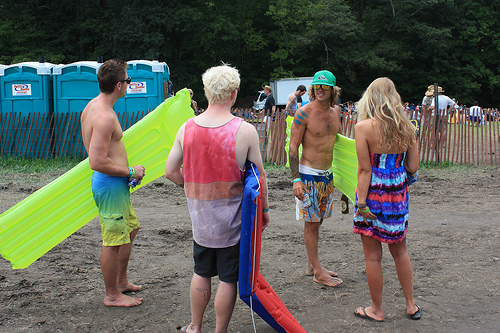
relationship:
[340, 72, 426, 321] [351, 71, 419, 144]
girl has hair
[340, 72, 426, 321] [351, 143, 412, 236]
girl wearing dress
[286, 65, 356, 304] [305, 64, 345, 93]
guy wearing hat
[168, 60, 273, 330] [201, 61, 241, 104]
guy has hair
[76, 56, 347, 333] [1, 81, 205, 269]
guy holding float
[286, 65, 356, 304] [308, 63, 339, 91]
guy wearing hat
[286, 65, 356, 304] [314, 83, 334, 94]
guy wearing goggles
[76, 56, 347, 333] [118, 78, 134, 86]
guy wearing glasses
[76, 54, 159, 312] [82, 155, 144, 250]
man wearing shorts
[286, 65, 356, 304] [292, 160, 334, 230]
guy wearing shorts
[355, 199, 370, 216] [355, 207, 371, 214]
bracelet on bracelet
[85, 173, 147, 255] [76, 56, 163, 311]
shorts worn by guy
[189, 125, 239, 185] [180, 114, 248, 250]
section of tank top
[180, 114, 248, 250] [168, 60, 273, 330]
tank top worn by guy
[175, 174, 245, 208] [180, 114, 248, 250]
section of tank top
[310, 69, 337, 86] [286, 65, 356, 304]
cap worn by guy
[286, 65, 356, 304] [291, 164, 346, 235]
guy in shorts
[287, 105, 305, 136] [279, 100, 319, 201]
stripes on arm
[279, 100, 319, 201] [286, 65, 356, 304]
arm of guy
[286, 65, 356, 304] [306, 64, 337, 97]
guy wearing hat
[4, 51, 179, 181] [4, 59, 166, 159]
potties in a potties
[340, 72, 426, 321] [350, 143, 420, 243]
girl in a dress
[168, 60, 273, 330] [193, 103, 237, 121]
guy with neck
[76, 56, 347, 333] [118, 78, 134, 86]
guy in glasses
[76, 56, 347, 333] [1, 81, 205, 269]
guy with float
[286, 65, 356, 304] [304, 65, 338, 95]
guy in cap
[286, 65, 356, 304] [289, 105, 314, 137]
guy with paint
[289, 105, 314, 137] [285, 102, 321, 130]
paint on shoulder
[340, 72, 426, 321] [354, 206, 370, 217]
girl wears bracelet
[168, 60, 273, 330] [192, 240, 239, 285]
guy wearing shorts